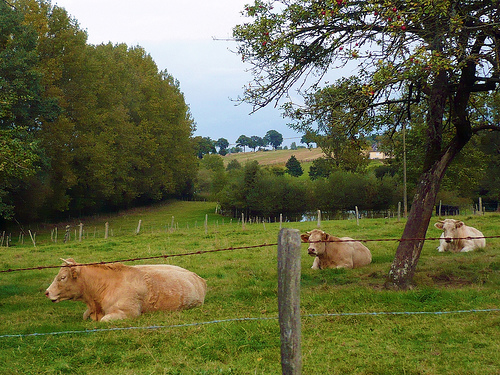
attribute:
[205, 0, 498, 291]
tree — leaning 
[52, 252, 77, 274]
horn — white, small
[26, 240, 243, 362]
cow — brown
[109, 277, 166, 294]
fur — brown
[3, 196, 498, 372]
grass — green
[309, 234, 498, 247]
barb wire — rusted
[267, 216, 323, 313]
post — wooden 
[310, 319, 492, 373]
grass — green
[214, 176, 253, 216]
bush — dark, green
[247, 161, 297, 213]
bush — dark, green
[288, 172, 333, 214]
bush — dark, green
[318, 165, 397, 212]
bush — dark, green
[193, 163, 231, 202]
bush — dark, green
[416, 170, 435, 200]
bark — brown 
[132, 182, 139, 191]
leaves — green